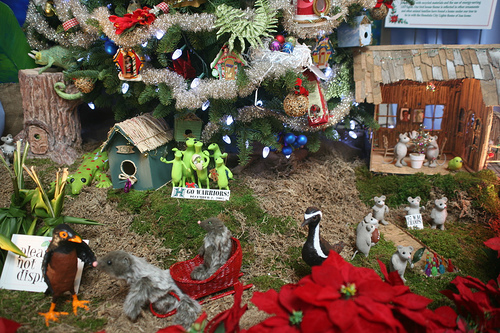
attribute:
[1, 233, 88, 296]
card — white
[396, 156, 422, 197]
ground — lizard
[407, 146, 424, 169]
pot — flower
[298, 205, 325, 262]
bird — black, white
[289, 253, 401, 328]
poinsettia — red, yellow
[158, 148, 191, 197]
teletubbie — green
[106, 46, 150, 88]
teletubbies — green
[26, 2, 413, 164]
christmas tree — decorated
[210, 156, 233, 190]
teletubbie — green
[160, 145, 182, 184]
teletubbie — green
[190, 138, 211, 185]
teletubbie — green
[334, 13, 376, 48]
birdhouse — small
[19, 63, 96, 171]
log — fake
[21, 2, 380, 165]
christmas tree — decorated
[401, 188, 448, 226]
teletubbies — green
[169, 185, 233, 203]
sign — "Go Warriors"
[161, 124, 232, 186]
green animal — figurines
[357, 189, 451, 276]
mice — gray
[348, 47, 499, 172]
wood house — miniature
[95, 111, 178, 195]
wood house — miniature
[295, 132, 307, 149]
ornaments — blue, round, for christmas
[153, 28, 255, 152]
lights — Christmas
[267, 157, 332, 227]
straw — dried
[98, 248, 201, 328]
stuffed animal — grey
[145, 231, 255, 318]
wicker sleigh — red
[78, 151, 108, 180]
spots — red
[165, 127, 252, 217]
teletubbies — green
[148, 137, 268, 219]
teletubbies — green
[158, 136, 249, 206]
teletubbies — green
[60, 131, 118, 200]
figure — green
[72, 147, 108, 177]
spots — red